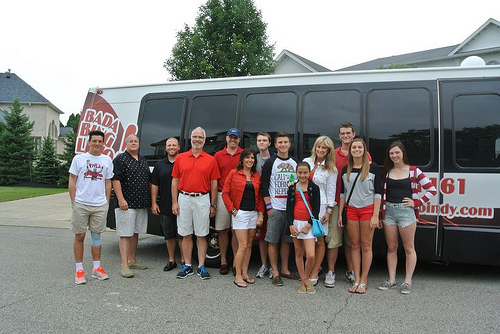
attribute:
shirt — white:
[337, 162, 386, 207]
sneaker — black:
[177, 264, 191, 279]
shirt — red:
[169, 144, 219, 194]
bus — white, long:
[67, 56, 499, 269]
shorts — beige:
[67, 199, 113, 244]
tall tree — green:
[165, 0, 281, 75]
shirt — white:
[68, 152, 113, 206]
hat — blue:
[226, 124, 250, 138]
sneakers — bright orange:
[56, 262, 110, 293]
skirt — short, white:
[229, 209, 261, 231]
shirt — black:
[110, 151, 150, 208]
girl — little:
[285, 161, 322, 291]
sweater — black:
[283, 177, 320, 224]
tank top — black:
[380, 167, 418, 202]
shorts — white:
[231, 201, 278, 238]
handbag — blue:
[296, 210, 343, 250]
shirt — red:
[207, 150, 238, 177]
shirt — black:
[145, 159, 176, 211]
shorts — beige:
[174, 189, 211, 236]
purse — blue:
[294, 181, 324, 237]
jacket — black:
[284, 178, 321, 225]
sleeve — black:
[375, 167, 385, 197]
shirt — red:
[334, 142, 349, 169]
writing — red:
[433, 178, 488, 221]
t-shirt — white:
[72, 157, 110, 207]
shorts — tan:
[173, 185, 209, 235]